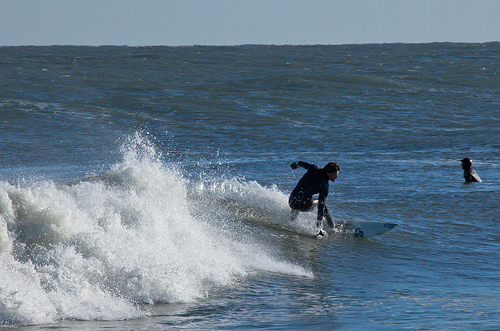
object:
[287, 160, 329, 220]
wetsuit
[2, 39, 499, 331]
water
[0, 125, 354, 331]
waves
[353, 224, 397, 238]
decals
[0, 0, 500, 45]
blue sky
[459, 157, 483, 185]
man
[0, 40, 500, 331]
ocean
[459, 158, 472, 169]
hat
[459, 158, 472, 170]
head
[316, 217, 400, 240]
surfboard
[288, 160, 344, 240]
man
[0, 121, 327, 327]
splash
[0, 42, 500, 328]
beach